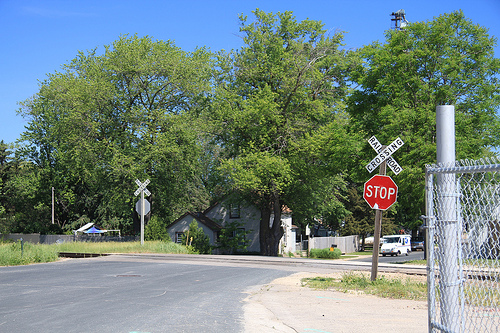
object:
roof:
[164, 206, 227, 231]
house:
[161, 197, 302, 256]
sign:
[364, 134, 406, 176]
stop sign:
[361, 173, 398, 212]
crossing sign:
[128, 175, 154, 198]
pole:
[369, 143, 387, 282]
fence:
[421, 157, 499, 332]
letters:
[362, 183, 397, 199]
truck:
[375, 232, 414, 258]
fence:
[5, 232, 139, 244]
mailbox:
[329, 243, 343, 250]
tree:
[205, 52, 361, 259]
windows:
[224, 199, 246, 221]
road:
[185, 253, 364, 271]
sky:
[10, 3, 102, 49]